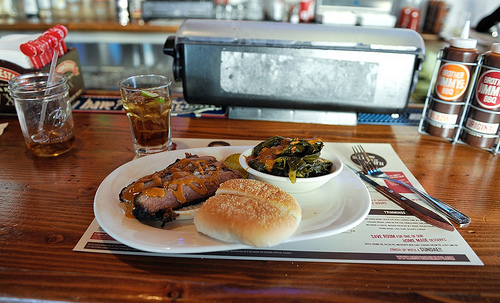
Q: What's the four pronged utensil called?
A: Fork.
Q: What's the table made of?
A: Wood.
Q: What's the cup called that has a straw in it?
A: Mason jar.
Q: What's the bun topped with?
A: Seeds.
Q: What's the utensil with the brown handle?
A: Knife.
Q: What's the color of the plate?
A: White.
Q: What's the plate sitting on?
A: Paper placemat.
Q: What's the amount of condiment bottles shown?
A: Two.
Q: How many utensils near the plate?
A: Two.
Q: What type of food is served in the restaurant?
A: BBQ.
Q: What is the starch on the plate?
A: Rolls.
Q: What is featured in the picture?
A: Food.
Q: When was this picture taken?
A: Daytime.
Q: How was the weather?
A: Sunny.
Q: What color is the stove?
A: Silver.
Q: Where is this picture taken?
A: In a restaurant.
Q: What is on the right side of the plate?
A: Sauces.